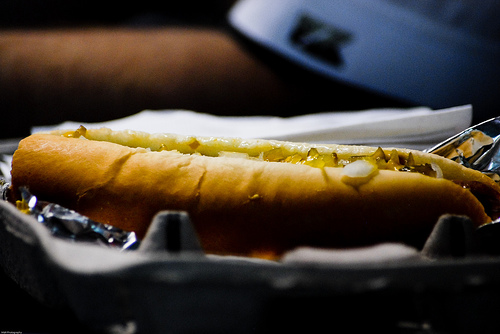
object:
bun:
[4, 120, 500, 263]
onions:
[339, 157, 378, 179]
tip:
[472, 167, 499, 225]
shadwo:
[250, 212, 314, 239]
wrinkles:
[188, 164, 211, 208]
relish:
[393, 149, 442, 179]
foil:
[32, 202, 140, 251]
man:
[0, 1, 500, 110]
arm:
[0, 21, 274, 108]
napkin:
[29, 102, 474, 152]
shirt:
[223, 0, 499, 110]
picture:
[0, 0, 497, 333]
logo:
[278, 6, 361, 73]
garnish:
[290, 140, 415, 186]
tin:
[0, 196, 499, 325]